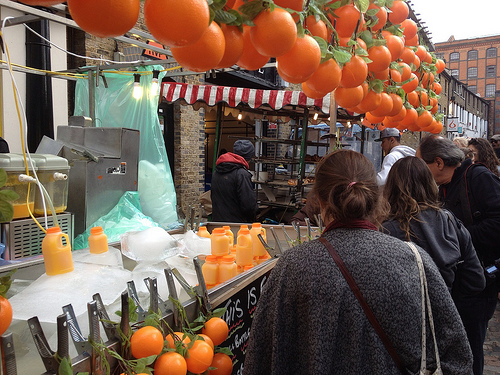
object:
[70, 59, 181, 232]
plastic bag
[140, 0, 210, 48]
oranges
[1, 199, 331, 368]
truck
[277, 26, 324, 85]
oranges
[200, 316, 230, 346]
oranges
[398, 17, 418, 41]
oranges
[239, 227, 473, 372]
sweater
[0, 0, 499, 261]
building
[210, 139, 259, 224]
man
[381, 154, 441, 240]
hair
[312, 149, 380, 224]
head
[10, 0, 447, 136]
decorative ranges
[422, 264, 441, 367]
straps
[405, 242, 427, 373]
straps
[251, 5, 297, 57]
orange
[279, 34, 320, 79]
orange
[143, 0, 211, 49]
orange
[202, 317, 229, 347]
orange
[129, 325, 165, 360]
orange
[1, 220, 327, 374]
truck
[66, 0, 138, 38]
oranges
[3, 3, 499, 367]
truck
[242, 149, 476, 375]
female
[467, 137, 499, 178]
person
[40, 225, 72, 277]
orange juice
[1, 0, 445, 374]
stall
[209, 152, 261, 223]
coat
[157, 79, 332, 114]
red white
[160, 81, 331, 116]
awning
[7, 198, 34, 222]
juice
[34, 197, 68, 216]
juice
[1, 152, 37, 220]
container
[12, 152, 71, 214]
container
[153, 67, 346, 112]
canopy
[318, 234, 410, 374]
purse strap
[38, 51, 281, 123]
conditioner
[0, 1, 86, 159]
window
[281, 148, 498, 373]
people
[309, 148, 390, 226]
hair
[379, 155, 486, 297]
people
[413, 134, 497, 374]
people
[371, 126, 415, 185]
people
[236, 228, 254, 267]
jug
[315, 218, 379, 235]
collar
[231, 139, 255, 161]
hat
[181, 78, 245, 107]
stripe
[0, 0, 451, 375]
shopping center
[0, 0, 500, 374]
business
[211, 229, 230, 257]
orange juice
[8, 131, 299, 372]
truck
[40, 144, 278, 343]
truck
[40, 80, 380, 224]
truck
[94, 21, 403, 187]
truck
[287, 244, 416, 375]
back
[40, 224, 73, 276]
jug